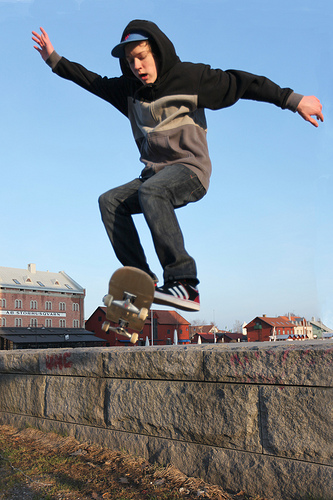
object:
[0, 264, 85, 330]
building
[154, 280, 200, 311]
shoe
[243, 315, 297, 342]
building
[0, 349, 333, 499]
stone wall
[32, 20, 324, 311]
boy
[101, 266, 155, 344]
skateboard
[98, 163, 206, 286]
blue jeans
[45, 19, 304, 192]
sweatshirt